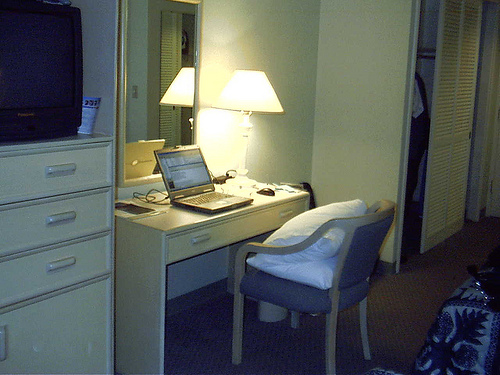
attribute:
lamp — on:
[209, 64, 287, 183]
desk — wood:
[111, 171, 314, 374]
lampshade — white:
[212, 64, 283, 118]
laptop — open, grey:
[152, 143, 256, 222]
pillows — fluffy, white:
[248, 198, 369, 287]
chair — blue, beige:
[228, 197, 396, 374]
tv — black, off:
[0, 0, 86, 145]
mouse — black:
[255, 185, 278, 200]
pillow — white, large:
[252, 253, 342, 291]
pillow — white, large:
[256, 195, 366, 261]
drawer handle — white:
[40, 161, 78, 176]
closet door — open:
[419, 1, 486, 256]